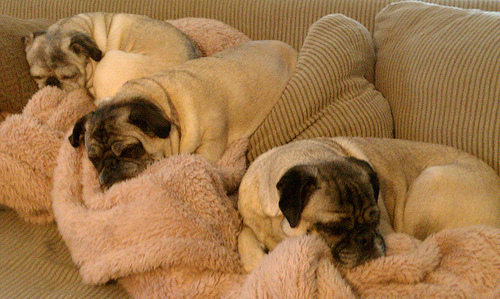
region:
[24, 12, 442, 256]
three dogs on a couch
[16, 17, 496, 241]
the dogs are sleeping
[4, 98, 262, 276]
the tiles are the same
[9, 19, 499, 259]
the dogs are cuddled up on the couch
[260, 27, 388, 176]
pillows on a couch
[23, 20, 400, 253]
the dogs look tired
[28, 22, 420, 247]
the dogs are comfortable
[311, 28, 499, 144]
the pillows are striped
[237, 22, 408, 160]
this pillow is crumpled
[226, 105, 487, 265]
this pooch is curled up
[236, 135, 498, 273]
a dog sleeping on a blanket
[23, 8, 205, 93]
a dog sleeping on a blanket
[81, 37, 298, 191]
a dog sleeping on a blanket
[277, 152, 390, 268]
the head of a dog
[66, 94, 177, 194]
the head of a dog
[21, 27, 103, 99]
the head of a dog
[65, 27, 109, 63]
the ear of a dog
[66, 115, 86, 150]
the ear of a dog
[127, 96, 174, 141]
the ear of a dog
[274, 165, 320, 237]
the ear of a dog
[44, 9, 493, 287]
dogs on a couch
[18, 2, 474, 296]
dogs on a blanket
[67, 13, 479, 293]
dogs on a pink blanket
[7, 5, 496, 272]
dogs on a plush blanket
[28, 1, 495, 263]
dogs on a blush pink blanket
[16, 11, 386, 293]
three dogs on a blanket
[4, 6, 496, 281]
three dogs on a plush blanket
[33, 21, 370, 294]
three dogs on a pink blacket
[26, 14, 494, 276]
three dogs sleeping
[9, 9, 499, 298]
three young bullmastiffs sleeping on a couch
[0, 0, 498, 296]
tan couch with brown stripes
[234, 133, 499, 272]
sleeping bullmastiff dog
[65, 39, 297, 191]
sleeping bullmastiff dog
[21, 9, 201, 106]
sleeping bullmastiff dog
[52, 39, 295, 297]
dog nestled into fleece blanket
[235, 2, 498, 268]
couch cushion behind fawn bullmastiff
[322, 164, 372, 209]
adorable forehead wrinkles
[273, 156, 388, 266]
dog's right ear is black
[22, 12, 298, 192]
dog sleeping behind dog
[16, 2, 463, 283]
3 dogs curled up on a couch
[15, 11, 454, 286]
3 dogs wrapped up in a blanket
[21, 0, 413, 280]
3 dogs wrapped up in a blanket on the couch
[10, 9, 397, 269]
3 pugs sleeping on a couch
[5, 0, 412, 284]
3 pugs sleeping on a couch wrapped in a beige blanket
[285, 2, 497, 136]
Brown beige sofa cushions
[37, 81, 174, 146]
Black pug dog ears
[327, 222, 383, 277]
Pug's mouth and nose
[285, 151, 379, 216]
Pug's wrinkly forehead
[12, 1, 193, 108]
Pug buried in a couch sleeping